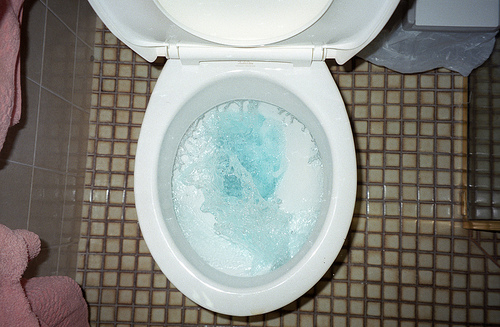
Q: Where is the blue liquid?
A: In the toilet.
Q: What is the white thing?
A: A toilet.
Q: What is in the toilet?
A: Cleaner.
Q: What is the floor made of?
A: Tiles.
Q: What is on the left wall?
A: A towel.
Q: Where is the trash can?
A: Beside the toilet.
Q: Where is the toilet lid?
A: Lifted up.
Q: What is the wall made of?
A: Tiles.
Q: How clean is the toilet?
A: Very clean.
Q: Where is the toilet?
A: In the bathroom.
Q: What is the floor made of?
A: Brown tiles.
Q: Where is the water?
A: In the toilet bowl.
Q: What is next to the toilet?
A: The trash can.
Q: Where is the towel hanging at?
A: The wall.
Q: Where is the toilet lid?
A: By the tank.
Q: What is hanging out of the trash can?
A: A trash bag.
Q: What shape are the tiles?
A: Square.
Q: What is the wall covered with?
A: Large tiles.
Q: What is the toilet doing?
A: Flushing.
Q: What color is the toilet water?
A: Blue.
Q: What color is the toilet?
A: White.